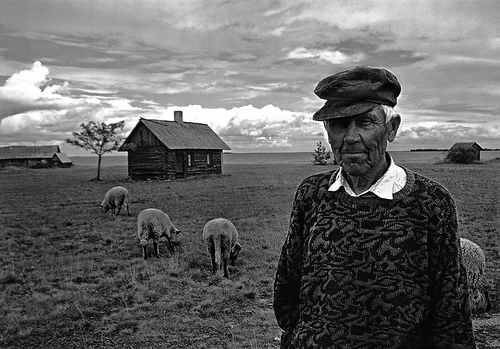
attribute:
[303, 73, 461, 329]
man — elderly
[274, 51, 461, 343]
man — elderly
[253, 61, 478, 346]
man — elderly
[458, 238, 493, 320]
sheep — grazing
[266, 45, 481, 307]
man — light skinned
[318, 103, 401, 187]
face — wrinkled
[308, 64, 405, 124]
cap — black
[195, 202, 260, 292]
sheep — furry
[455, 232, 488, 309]
sheep — furry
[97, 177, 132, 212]
sheep — furry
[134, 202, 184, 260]
sheep — furry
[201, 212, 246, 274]
sheep — furry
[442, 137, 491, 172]
hut — small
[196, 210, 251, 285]
sheep — grazing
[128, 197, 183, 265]
sheep — grazing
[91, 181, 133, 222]
sheep — grazing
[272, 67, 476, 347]
man — old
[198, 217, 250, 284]
sheep — feeding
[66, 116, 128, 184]
tree — small